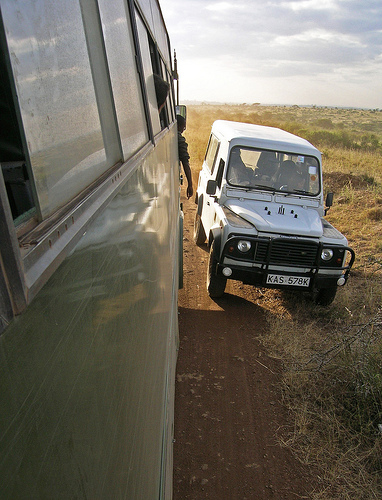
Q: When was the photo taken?
A: Daytime.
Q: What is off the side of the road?
A: A Jeep.